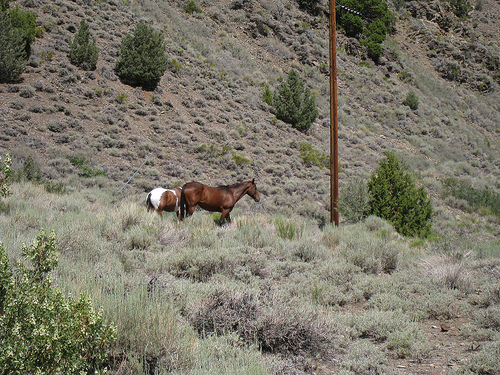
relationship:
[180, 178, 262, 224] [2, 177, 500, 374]
horse on hill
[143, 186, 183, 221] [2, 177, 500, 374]
horse on hill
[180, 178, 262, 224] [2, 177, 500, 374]
horses are on hill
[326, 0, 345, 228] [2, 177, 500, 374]
pole on hill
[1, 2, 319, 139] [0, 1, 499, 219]
bushes on a hill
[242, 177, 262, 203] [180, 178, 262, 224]
head of horse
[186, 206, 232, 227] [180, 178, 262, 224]
legs of a horse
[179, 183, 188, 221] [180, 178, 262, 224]
tail of horse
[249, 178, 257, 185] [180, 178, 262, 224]
ear of horse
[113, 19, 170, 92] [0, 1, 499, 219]
bush on hill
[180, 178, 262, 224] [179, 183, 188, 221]
horse with tail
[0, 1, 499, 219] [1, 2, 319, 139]
hill with bushes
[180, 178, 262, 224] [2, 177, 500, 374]
horse descending from hill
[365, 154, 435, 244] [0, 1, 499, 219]
tree on hillside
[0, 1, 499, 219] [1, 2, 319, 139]
field with bushes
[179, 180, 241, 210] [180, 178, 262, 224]
body of horse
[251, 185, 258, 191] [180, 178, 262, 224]
eye of horse